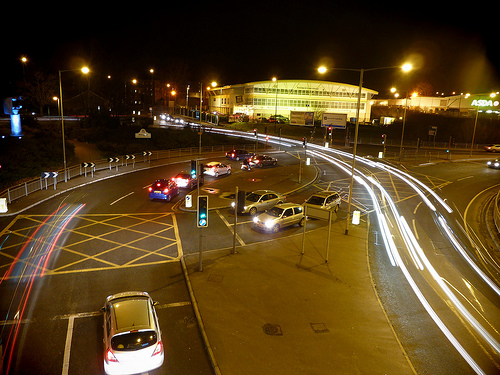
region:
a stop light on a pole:
[187, 196, 217, 273]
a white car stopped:
[99, 293, 165, 368]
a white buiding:
[225, 81, 369, 126]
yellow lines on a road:
[71, 207, 180, 274]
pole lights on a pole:
[307, 60, 416, 228]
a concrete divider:
[181, 214, 386, 357]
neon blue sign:
[4, 101, 26, 146]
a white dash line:
[409, 195, 424, 247]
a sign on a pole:
[291, 203, 338, 271]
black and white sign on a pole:
[43, 171, 61, 181]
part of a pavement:
[353, 277, 366, 294]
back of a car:
[145, 343, 152, 344]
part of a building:
[316, 88, 324, 97]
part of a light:
[263, 224, 276, 234]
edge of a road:
[348, 249, 380, 294]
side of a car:
[153, 313, 158, 323]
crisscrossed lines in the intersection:
[1, 165, 453, 280]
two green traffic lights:
[187, 155, 209, 230]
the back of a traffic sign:
[301, 200, 335, 222]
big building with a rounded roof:
[202, 75, 378, 130]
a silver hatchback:
[251, 199, 307, 236]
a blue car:
[145, 177, 178, 206]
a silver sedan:
[233, 188, 288, 215]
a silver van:
[303, 187, 344, 217]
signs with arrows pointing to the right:
[36, 149, 154, 182]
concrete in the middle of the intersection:
[179, 211, 418, 372]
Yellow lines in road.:
[82, 207, 198, 303]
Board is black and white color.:
[36, 150, 161, 182]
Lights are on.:
[27, 41, 439, 131]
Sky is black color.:
[145, 10, 415, 55]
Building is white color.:
[202, 80, 407, 146]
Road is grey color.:
[24, 278, 179, 322]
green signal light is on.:
[185, 185, 234, 247]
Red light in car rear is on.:
[143, 143, 270, 223]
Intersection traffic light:
[196, 192, 213, 230]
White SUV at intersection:
[100, 289, 170, 374]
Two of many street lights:
[303, 37, 432, 83]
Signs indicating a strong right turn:
[40, 142, 160, 191]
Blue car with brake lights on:
[147, 173, 177, 208]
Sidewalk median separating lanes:
[180, 220, 414, 373]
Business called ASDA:
[381, 84, 498, 116]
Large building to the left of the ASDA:
[188, 60, 377, 133]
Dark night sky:
[5, 0, 494, 82]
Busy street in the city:
[0, 0, 498, 373]